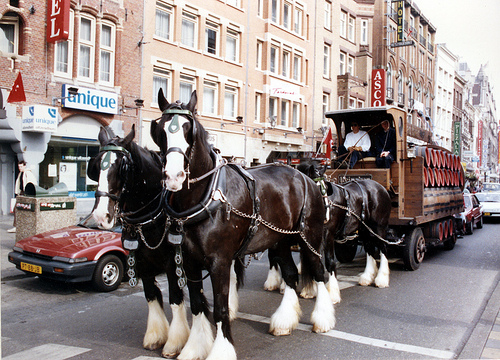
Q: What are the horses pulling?
A: A beer wagon.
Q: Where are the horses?
A: On a street.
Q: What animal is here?
A: Horses.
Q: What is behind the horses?
A: Carriage.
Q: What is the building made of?
A: Brick.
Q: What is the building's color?
A: Red.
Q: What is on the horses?
A: Chains.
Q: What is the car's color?
A: Red.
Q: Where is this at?
A: Street.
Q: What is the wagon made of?
A: Wood.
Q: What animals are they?
A: Horses.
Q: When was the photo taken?
A: Daytime.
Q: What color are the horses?
A: Black and white.